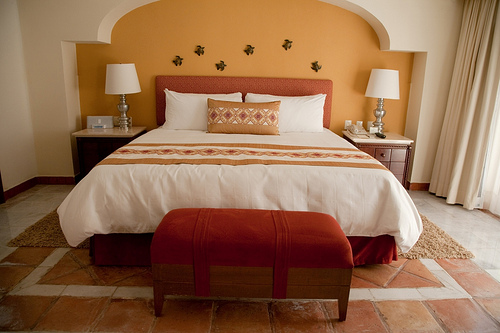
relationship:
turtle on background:
[172, 56, 184, 67] [82, 15, 415, 84]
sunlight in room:
[175, 40, 492, 300] [1, 10, 497, 331]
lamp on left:
[364, 68, 400, 133] [349, 56, 415, 180]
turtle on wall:
[172, 56, 184, 67] [82, 15, 415, 84]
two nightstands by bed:
[19, 122, 415, 187] [52, 66, 403, 253]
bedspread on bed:
[46, 117, 384, 232] [52, 66, 403, 253]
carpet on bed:
[410, 231, 485, 267] [52, 66, 403, 253]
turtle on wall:
[172, 56, 184, 67] [25, 0, 487, 74]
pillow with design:
[206, 92, 289, 139] [194, 106, 275, 129]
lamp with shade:
[102, 59, 143, 133] [99, 59, 142, 103]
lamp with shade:
[358, 61, 405, 132] [360, 65, 405, 112]